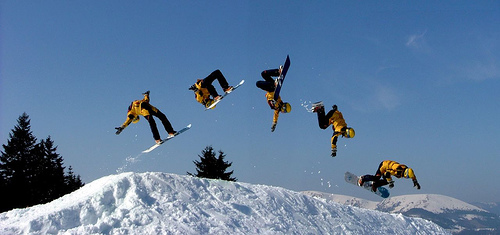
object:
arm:
[120, 111, 135, 128]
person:
[252, 54, 299, 132]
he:
[107, 82, 196, 162]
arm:
[142, 89, 152, 103]